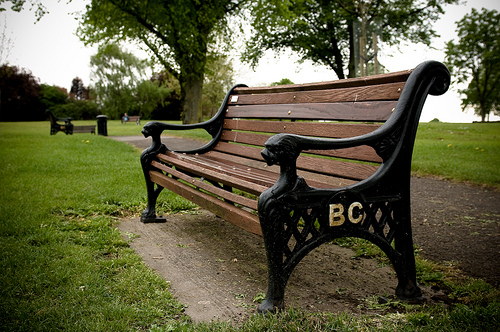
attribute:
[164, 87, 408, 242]
bench — outdoor, brown, sitting, here, wood, wooden, iron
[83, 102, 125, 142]
can — metal, black, trash, along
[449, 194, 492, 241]
path — paved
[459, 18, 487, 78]
tree — green, large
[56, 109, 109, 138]
bench — distant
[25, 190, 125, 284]
grass — green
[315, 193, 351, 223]
letters — b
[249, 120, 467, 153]
rest — metal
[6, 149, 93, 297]
field — green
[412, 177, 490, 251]
trail — gravel, gray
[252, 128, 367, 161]
handles — black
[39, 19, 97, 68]
sky — here, full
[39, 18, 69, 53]
cloud — white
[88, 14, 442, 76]
trees — several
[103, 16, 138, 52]
leaves — green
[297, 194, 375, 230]
bc — written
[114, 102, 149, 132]
person — sitting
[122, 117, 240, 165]
sidewalk — behind